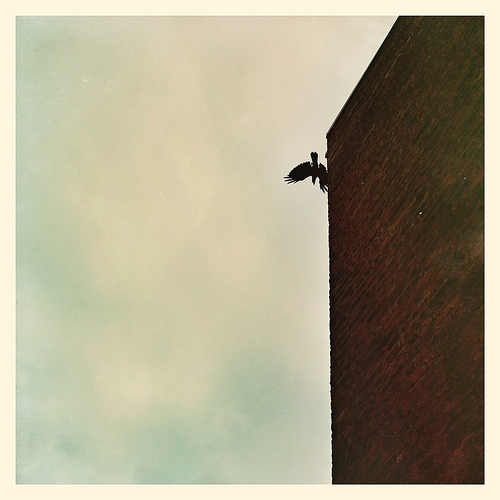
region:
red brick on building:
[372, 271, 383, 281]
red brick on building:
[383, 334, 403, 350]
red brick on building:
[415, 306, 431, 323]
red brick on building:
[346, 306, 368, 329]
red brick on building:
[425, 273, 460, 306]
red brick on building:
[413, 456, 440, 476]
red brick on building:
[419, 459, 449, 479]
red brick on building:
[441, 408, 479, 455]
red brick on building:
[372, 428, 402, 448]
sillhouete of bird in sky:
[274, 148, 334, 196]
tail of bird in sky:
[301, 145, 321, 162]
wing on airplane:
[278, 155, 310, 189]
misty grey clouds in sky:
[23, 24, 223, 224]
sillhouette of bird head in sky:
[306, 177, 317, 187]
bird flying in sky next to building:
[271, 17, 491, 483]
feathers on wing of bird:
[281, 174, 297, 188]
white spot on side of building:
[409, 204, 428, 225]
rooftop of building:
[301, 14, 393, 146]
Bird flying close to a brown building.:
[266, 158, 328, 195]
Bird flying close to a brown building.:
[346, 269, 397, 361]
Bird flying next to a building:
[281, 145, 328, 194]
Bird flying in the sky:
[283, 147, 328, 195]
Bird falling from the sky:
[282, 148, 328, 194]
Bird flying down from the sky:
[280, 147, 328, 196]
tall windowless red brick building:
[323, 15, 484, 481]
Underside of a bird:
[284, 148, 329, 194]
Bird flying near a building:
[282, 148, 328, 194]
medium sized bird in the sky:
[282, 148, 329, 195]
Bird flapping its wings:
[279, 149, 329, 196]